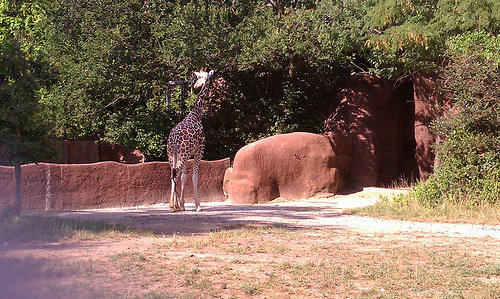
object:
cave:
[322, 60, 474, 196]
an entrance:
[370, 73, 422, 188]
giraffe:
[166, 68, 218, 212]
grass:
[0, 208, 499, 298]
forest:
[0, 0, 499, 217]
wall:
[222, 131, 340, 205]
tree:
[0, 20, 63, 218]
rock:
[220, 131, 354, 206]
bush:
[341, 161, 499, 224]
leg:
[192, 153, 203, 205]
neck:
[185, 81, 212, 118]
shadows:
[0, 202, 346, 251]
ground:
[59, 198, 499, 238]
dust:
[0, 168, 110, 298]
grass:
[355, 204, 499, 218]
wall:
[415, 70, 482, 191]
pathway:
[249, 185, 408, 234]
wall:
[0, 156, 230, 216]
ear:
[209, 69, 216, 78]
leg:
[180, 157, 188, 205]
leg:
[169, 156, 182, 204]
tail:
[172, 140, 179, 194]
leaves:
[5, 45, 39, 118]